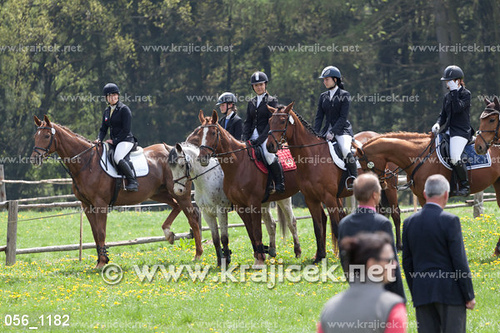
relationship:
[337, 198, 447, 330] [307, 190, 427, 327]
head of man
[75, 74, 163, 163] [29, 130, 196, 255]
rider on horse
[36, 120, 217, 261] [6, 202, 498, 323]
horse standing in grass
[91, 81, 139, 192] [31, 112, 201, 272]
rider on top of horse